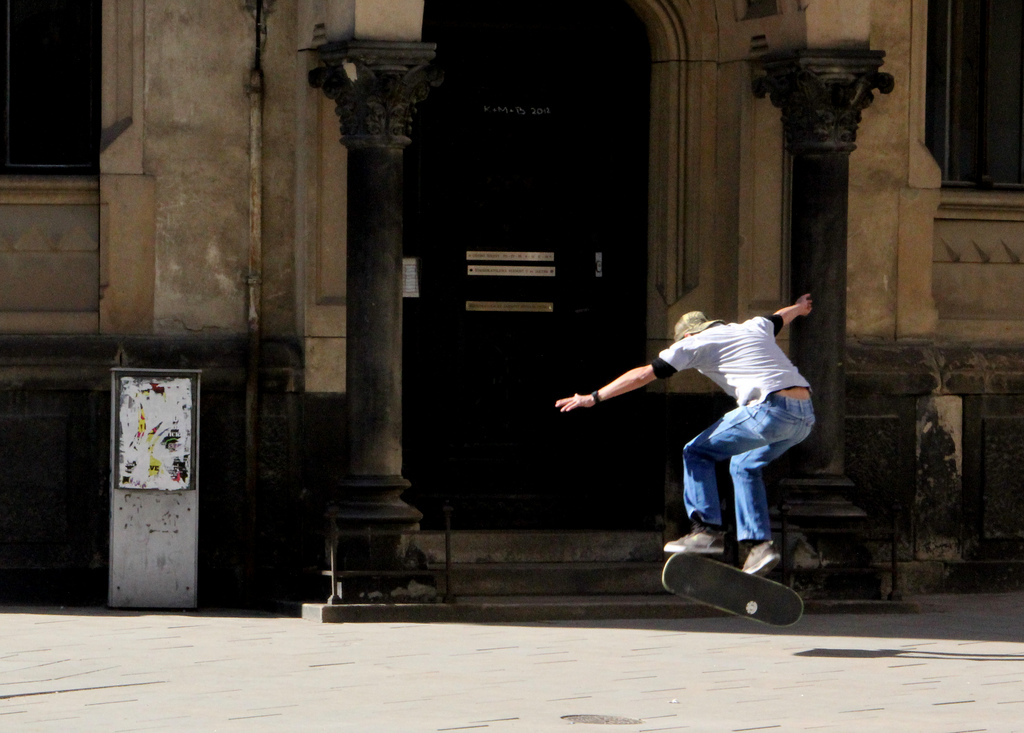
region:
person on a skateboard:
[551, 298, 833, 627]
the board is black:
[661, 551, 798, 632]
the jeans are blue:
[678, 397, 812, 544]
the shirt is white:
[658, 314, 804, 407]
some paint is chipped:
[115, 375, 192, 492]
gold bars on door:
[465, 254, 557, 313]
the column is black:
[299, 33, 445, 610]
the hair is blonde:
[675, 314, 721, 338]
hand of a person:
[552, 394, 592, 413]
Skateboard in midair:
[662, 554, 803, 628]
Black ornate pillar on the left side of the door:
[310, 35, 441, 601]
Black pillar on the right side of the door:
[756, 47, 889, 588]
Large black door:
[419, 0, 653, 525]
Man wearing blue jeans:
[684, 398, 814, 564]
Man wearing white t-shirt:
[652, 319, 811, 390]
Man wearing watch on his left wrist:
[590, 391, 601, 405]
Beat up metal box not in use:
[106, 364, 198, 608]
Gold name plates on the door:
[465, 249, 554, 314]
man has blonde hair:
[667, 300, 713, 346]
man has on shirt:
[657, 312, 822, 417]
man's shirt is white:
[662, 312, 821, 414]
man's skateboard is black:
[646, 542, 811, 645]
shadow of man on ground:
[790, 628, 1021, 670]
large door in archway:
[387, 3, 694, 541]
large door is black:
[383, 2, 694, 535]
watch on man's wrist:
[583, 384, 609, 420]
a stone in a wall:
[13, 257, 102, 309]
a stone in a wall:
[18, 304, 101, 328]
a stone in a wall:
[89, 244, 163, 334]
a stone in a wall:
[94, 159, 165, 252]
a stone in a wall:
[103, 9, 145, 183]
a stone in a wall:
[152, 267, 252, 344]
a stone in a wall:
[312, 333, 360, 409]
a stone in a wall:
[885, 191, 946, 348]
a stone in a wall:
[809, 0, 858, 45]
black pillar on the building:
[310, 42, 437, 596]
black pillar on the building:
[756, 40, 875, 591]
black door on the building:
[419, 15, 631, 521]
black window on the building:
[927, 12, 1020, 191]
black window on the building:
[1, 0, 100, 178]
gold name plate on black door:
[459, 246, 557, 266]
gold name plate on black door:
[463, 258, 555, 281]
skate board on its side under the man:
[652, 538, 809, 631]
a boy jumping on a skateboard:
[540, 285, 834, 641]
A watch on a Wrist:
[566, 374, 611, 416]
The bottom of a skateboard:
[660, 544, 813, 627]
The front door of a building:
[413, 4, 663, 537]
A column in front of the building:
[297, 25, 452, 627]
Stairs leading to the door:
[430, 511, 668, 604]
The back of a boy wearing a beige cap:
[660, 304, 815, 385]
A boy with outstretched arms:
[555, 290, 835, 417]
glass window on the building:
[946, 78, 981, 124]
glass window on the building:
[955, 36, 990, 81]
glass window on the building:
[993, 96, 1016, 131]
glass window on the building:
[43, 119, 95, 171]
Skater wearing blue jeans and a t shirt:
[540, 254, 867, 632]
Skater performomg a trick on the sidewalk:
[517, 263, 898, 640]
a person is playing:
[549, 296, 812, 571]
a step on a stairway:
[303, 599, 929, 618]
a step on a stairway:
[315, 564, 892, 600]